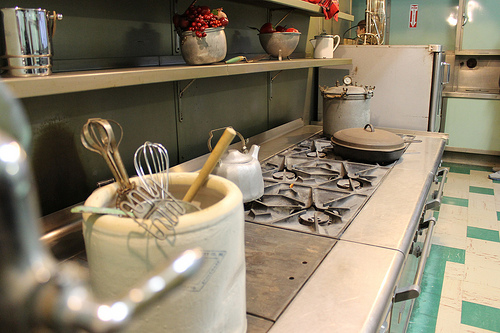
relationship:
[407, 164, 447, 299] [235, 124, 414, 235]
handles on burner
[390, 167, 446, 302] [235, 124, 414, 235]
handles on burner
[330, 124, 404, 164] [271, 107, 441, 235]
pan on stove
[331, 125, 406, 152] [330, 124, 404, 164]
lid on pan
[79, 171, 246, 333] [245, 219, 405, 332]
ceramic jar on counter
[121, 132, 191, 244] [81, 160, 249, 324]
potato masher in crock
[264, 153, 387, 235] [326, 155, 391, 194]
burner on a stove top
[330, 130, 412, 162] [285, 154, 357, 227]
pan on a stove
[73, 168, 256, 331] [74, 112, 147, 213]
ceramic jar containing utensil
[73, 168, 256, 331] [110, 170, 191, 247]
ceramic jar containing utensil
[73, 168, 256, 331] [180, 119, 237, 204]
ceramic jar containing utensil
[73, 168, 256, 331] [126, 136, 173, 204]
ceramic jar containing utensil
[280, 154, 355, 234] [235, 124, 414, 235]
iron burners on burner